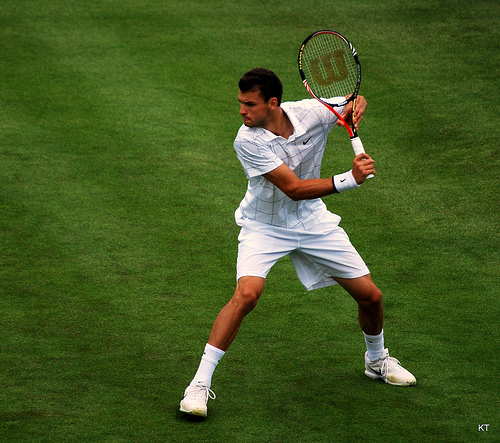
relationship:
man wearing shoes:
[211, 42, 403, 299] [365, 364, 418, 389]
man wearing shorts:
[211, 42, 403, 299] [245, 240, 284, 269]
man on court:
[211, 42, 403, 299] [37, 72, 198, 251]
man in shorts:
[211, 42, 403, 299] [245, 240, 284, 269]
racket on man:
[295, 32, 391, 149] [211, 42, 403, 299]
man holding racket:
[211, 42, 403, 299] [295, 32, 391, 149]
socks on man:
[188, 346, 231, 373] [211, 42, 403, 299]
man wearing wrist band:
[211, 42, 403, 299] [329, 167, 364, 196]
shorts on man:
[245, 240, 284, 269] [211, 42, 403, 299]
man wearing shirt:
[211, 42, 403, 299] [256, 137, 331, 215]